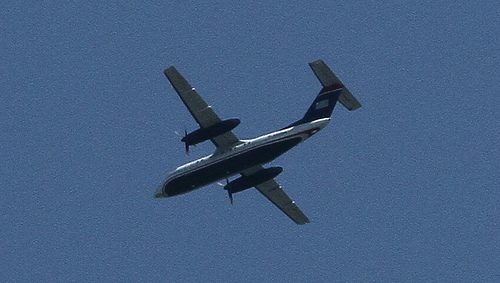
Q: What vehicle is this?
A: Airplane.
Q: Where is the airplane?
A: Sky.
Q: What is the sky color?
A: Blue.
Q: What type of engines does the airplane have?
A: Propeller.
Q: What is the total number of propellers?
A: 2.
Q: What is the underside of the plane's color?
A: Black.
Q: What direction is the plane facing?
A: Left.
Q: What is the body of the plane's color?
A: White.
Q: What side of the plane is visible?
A: Bottom.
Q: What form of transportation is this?
A: Airplane.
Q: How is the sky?
A: Clear blue.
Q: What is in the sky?
A: A plane.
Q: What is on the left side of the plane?
A: A wing.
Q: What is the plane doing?
A: Flying.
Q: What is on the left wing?
A: An engine.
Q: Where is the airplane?
A: In the air.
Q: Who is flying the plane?
A: A pilot.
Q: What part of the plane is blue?
A: The bottom.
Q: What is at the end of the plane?
A: A tail.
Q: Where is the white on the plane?
A: On the wings.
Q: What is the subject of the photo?
A: Plane.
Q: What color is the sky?
A: Blue.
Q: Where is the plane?
A: Sky.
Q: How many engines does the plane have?
A: Two.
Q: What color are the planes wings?
A: White.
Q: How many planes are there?
A: One.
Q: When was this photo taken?
A: Daytime.